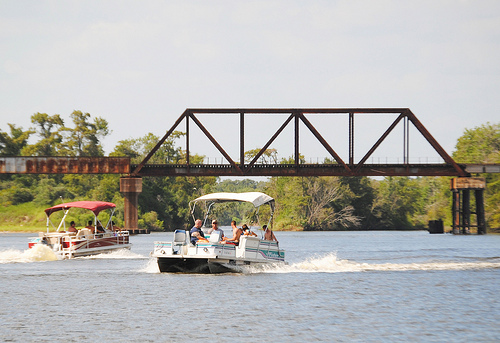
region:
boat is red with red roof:
[24, 177, 135, 264]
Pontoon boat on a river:
[21, 196, 136, 262]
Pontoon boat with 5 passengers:
[148, 184, 294, 286]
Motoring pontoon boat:
[151, 184, 291, 284]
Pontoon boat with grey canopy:
[151, 181, 293, 280]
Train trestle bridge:
[106, 84, 499, 234]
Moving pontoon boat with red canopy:
[14, 191, 141, 273]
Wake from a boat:
[284, 247, 379, 281]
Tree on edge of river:
[286, 176, 392, 231]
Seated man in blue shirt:
[186, 217, 209, 246]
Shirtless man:
[226, 217, 243, 249]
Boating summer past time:
[25, 178, 332, 305]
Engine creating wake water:
[7, 203, 68, 266]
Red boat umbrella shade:
[36, 195, 134, 260]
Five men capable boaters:
[152, 192, 308, 277]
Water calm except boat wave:
[280, 238, 492, 338]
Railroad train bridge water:
[127, 104, 470, 182]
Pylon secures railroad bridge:
[446, 165, 490, 242]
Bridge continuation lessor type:
[0, 145, 139, 185]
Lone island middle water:
[274, 176, 420, 240]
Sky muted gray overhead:
[71, 6, 474, 81]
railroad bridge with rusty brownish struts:
[127, 98, 475, 190]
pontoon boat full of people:
[155, 183, 290, 279]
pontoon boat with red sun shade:
[35, 195, 139, 267]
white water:
[292, 243, 381, 297]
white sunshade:
[185, 182, 290, 220]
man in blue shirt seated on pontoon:
[187, 216, 213, 248]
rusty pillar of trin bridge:
[438, 169, 489, 244]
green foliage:
[12, 186, 102, 206]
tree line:
[449, 113, 496, 162]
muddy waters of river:
[331, 285, 446, 333]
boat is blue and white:
[151, 177, 298, 282]